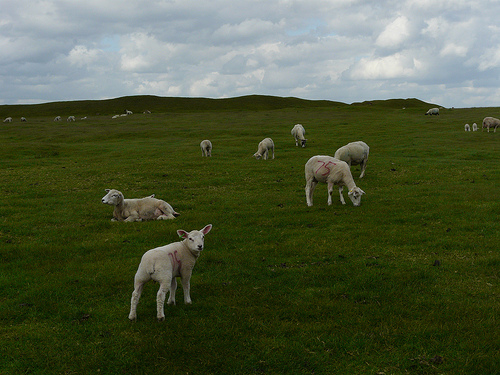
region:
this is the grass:
[281, 318, 378, 363]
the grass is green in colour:
[287, 315, 374, 342]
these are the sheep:
[104, 190, 209, 372]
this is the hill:
[107, 96, 198, 106]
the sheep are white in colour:
[100, 175, 225, 330]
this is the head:
[177, 224, 217, 256]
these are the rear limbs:
[110, 268, 175, 342]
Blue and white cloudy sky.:
[2, 2, 499, 107]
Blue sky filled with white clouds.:
[2, 1, 499, 106]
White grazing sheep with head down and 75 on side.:
[303, 154, 366, 206]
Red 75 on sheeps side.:
[313, 158, 334, 178]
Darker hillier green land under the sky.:
[1, 93, 449, 115]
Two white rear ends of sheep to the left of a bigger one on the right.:
[463, 122, 478, 132]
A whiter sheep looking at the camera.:
[127, 224, 214, 320]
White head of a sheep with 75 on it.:
[348, 185, 365, 205]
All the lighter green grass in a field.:
[1, 109, 499, 374]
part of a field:
[263, 181, 367, 296]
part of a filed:
[322, 289, 362, 330]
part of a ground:
[348, 313, 375, 359]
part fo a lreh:
[153, 305, 168, 328]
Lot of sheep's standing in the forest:
[3, 91, 498, 366]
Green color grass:
[283, 255, 429, 337]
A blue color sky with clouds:
[226, 16, 459, 81]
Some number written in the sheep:
[314, 148, 339, 181]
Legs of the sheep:
[296, 183, 344, 210]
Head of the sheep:
[345, 179, 369, 213]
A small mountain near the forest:
[4, 88, 433, 114]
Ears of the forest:
[174, 223, 218, 242]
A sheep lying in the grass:
[95, 180, 186, 225]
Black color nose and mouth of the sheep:
[196, 239, 208, 254]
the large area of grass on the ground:
[0, 93, 498, 373]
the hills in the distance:
[0, 94, 448, 114]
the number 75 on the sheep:
[313, 159, 336, 176]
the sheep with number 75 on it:
[302, 155, 365, 209]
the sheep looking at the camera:
[127, 223, 211, 319]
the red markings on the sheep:
[168, 249, 182, 273]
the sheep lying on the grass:
[101, 188, 181, 222]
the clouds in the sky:
[0, 0, 499, 108]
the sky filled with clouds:
[0, 0, 499, 105]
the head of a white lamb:
[167, 215, 211, 263]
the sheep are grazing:
[87, 103, 416, 368]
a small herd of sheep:
[45, 91, 427, 347]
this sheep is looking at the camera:
[122, 218, 259, 335]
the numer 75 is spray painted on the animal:
[284, 138, 386, 235]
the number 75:
[306, 152, 349, 187]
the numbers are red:
[275, 147, 387, 232]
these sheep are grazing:
[221, 115, 415, 240]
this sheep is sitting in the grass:
[91, 168, 190, 253]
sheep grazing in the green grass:
[248, 94, 390, 234]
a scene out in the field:
[21, 88, 475, 312]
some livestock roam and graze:
[14, 88, 496, 328]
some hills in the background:
[13, 73, 495, 158]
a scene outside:
[43, 17, 488, 342]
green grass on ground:
[8, 95, 498, 368]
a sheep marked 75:
[288, 146, 395, 241]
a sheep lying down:
[63, 186, 192, 245]